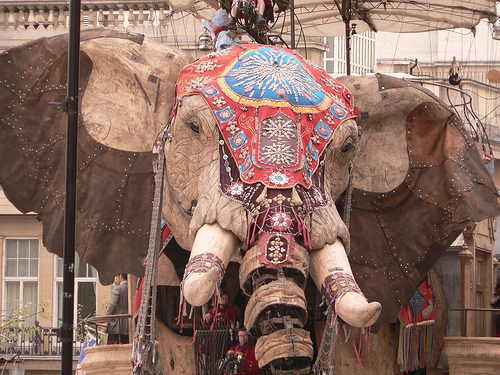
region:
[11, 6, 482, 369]
elephant with tusks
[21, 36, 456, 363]
elephant dressed with lots of ornate fabric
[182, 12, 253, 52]
person sitting on top of elephant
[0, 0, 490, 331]
buildings behind the elephant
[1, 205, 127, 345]
man standing on balcony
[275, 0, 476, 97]
umbrella above elephant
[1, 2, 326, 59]
balcony of a building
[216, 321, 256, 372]
man watching inside of elephant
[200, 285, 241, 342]
man standing on a balcony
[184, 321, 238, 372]
railing of a balcony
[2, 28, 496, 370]
elephant head and body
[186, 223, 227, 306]
elephant tusk of ivory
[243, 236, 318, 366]
elephant trunk made of cloth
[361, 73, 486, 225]
elephant ears made from fabric sewn together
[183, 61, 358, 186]
elephant forehead made from colorful red and blue fabric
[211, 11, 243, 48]
man in white gown and cap riding on elephant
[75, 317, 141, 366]
balcony of building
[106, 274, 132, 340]
man standing on balcony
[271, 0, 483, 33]
large sail with strings dangling from it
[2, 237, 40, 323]
window with curtains pulled closed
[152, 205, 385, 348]
Two white tusks on elephant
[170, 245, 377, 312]
Brown decorations on elephant tusks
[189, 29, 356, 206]
Red and blue hat on elephant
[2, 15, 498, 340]
Two brown elephant ears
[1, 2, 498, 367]
Tan building in the background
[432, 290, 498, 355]
Silver railing on the building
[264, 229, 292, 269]
Brown and white diamonds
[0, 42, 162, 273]
White dots on elephant ears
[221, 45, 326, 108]
Blue circle designs on elephant hat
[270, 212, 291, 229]
White flower design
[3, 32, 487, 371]
Large mechanical elephant with people inside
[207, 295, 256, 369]
Two people inside of the elephant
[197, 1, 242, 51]
A person standing on the elephant's head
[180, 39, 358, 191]
Decorative cloth on the head of the elephant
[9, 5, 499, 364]
Several buildings behind the elephant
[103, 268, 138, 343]
A man standing on the balcony of one of the buildings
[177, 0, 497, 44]
An awning over the elephant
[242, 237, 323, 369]
The exposed mechanical parts of the trunk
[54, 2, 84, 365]
A pole holding up the awning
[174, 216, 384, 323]
The elephants tusks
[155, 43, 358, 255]
Head of an elephant statue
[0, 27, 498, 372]
Statue of an elephant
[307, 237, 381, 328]
One of the two tusks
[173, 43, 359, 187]
A decorative red cloth on elephant head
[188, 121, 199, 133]
Right eye of the elephant statue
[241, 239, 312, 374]
Trunk of the elephant statue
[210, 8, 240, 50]
A person on elephant's back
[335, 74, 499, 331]
The huge left ear of the elephant statue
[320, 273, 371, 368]
Decorative cloth ribbons and strings on the tusk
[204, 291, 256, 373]
A woman and a man under the statue